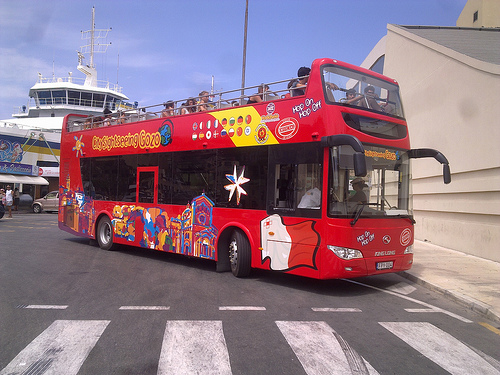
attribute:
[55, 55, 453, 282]
bus — red, double decker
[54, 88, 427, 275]
bus — big, red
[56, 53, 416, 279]
bus — full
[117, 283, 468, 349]
road — marked, grey, tarmac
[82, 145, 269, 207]
windows — tinted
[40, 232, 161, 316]
tarmac — grey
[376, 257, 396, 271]
license plate — rectangular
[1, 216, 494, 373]
road — grey, tarmac, marked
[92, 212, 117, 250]
tire — black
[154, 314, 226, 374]
line — white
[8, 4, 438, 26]
sky. — blue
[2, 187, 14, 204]
shirt — white